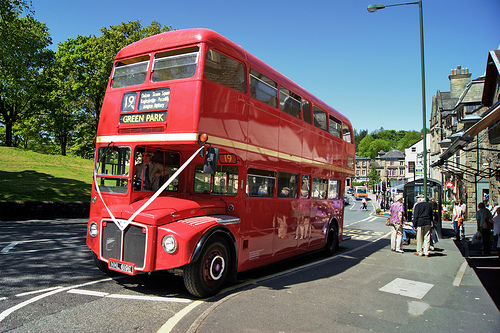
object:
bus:
[85, 26, 356, 297]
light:
[367, 0, 427, 201]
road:
[0, 186, 496, 332]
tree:
[0, 0, 56, 144]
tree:
[51, 36, 119, 121]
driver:
[127, 151, 172, 190]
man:
[412, 195, 432, 256]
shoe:
[414, 252, 423, 256]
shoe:
[425, 253, 430, 257]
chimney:
[448, 64, 472, 98]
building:
[427, 44, 499, 228]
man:
[285, 92, 301, 119]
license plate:
[106, 260, 135, 274]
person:
[388, 195, 406, 253]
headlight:
[161, 234, 178, 254]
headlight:
[88, 222, 100, 238]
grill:
[101, 222, 147, 268]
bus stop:
[387, 178, 443, 240]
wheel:
[183, 237, 230, 297]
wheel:
[326, 224, 338, 257]